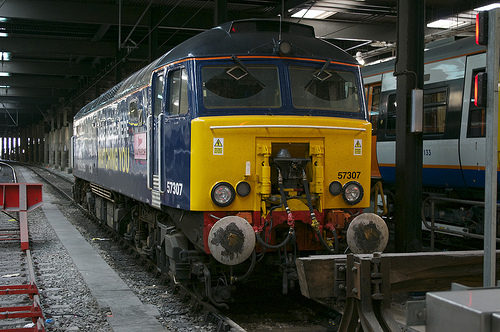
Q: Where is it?
A: This is at the parking lot.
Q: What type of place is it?
A: It is a parking lot.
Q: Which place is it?
A: It is a parking lot.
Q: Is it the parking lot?
A: Yes, it is the parking lot.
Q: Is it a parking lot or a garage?
A: It is a parking lot.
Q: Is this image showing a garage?
A: No, the picture is showing a parking lot.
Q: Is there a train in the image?
A: Yes, there is a train.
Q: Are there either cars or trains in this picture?
A: Yes, there is a train.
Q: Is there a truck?
A: No, there are no trucks.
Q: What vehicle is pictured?
A: The vehicle is a train.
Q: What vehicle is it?
A: The vehicle is a train.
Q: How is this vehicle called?
A: This is a train.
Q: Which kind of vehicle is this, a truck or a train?
A: This is a train.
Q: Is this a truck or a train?
A: This is a train.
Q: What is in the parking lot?
A: The train is in the parking lot.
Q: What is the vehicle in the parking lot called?
A: The vehicle is a train.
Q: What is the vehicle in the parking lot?
A: The vehicle is a train.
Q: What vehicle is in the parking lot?
A: The vehicle is a train.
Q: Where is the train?
A: The train is in the parking lot.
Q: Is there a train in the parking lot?
A: Yes, there is a train in the parking lot.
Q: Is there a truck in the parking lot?
A: No, there is a train in the parking lot.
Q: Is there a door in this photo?
A: Yes, there is a door.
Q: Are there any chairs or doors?
A: Yes, there is a door.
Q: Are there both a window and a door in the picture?
A: Yes, there are both a door and a window.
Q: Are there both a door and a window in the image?
A: Yes, there are both a door and a window.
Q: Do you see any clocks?
A: No, there are no clocks.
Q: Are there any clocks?
A: No, there are no clocks.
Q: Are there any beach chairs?
A: No, there are no beach chairs.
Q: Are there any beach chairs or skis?
A: No, there are no beach chairs or skis.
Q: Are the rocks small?
A: Yes, the rocks are small.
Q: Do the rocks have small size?
A: Yes, the rocks are small.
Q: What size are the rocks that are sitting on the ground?
A: The rocks are small.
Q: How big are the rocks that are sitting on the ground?
A: The rocks are small.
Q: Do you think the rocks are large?
A: No, the rocks are small.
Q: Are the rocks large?
A: No, the rocks are small.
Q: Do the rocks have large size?
A: No, the rocks are small.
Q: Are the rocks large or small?
A: The rocks are small.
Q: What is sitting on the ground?
A: The rocks are sitting on the ground.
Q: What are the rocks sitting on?
A: The rocks are sitting on the ground.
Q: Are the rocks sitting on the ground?
A: Yes, the rocks are sitting on the ground.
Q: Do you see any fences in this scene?
A: No, there are no fences.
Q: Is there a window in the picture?
A: Yes, there is a window.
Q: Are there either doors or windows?
A: Yes, there is a window.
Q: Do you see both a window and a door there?
A: Yes, there are both a window and a door.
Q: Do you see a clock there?
A: No, there are no clocks.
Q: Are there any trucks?
A: No, there are no trucks.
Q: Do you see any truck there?
A: No, there are no trucks.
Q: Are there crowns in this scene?
A: No, there are no crowns.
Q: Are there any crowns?
A: No, there are no crowns.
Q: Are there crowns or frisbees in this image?
A: No, there are no crowns or frisbees.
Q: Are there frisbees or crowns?
A: No, there are no crowns or frisbees.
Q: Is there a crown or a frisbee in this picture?
A: No, there are no crowns or frisbees.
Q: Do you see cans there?
A: No, there are no cans.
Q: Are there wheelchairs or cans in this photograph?
A: No, there are no cans or wheelchairs.